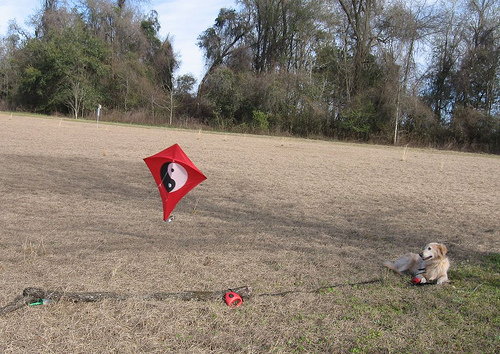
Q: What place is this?
A: It is a field.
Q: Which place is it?
A: It is a field.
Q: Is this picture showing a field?
A: Yes, it is showing a field.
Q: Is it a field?
A: Yes, it is a field.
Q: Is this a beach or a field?
A: It is a field.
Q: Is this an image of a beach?
A: No, the picture is showing a field.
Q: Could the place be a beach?
A: No, it is a field.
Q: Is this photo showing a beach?
A: No, the picture is showing a field.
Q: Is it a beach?
A: No, it is a field.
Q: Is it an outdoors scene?
A: Yes, it is outdoors.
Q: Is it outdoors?
A: Yes, it is outdoors.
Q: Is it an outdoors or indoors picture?
A: It is outdoors.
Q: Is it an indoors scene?
A: No, it is outdoors.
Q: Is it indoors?
A: No, it is outdoors.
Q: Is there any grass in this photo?
A: Yes, there is grass.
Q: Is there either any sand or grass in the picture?
A: Yes, there is grass.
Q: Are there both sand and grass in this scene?
A: No, there is grass but no sand.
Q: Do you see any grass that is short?
A: Yes, there is short grass.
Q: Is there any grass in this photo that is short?
A: Yes, there is grass that is short.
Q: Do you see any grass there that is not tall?
A: Yes, there is short grass.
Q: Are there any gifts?
A: No, there are no gifts.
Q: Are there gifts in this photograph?
A: No, there are no gifts.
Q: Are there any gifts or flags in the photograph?
A: No, there are no gifts or flags.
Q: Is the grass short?
A: Yes, the grass is short.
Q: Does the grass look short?
A: Yes, the grass is short.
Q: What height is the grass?
A: The grass is short.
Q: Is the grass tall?
A: No, the grass is short.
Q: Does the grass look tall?
A: No, the grass is short.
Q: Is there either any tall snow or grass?
A: No, there is grass but it is short.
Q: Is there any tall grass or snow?
A: No, there is grass but it is short.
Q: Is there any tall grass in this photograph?
A: No, there is grass but it is short.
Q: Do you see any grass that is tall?
A: No, there is grass but it is short.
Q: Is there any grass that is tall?
A: No, there is grass but it is short.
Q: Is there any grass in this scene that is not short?
A: No, there is grass but it is short.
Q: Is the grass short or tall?
A: The grass is short.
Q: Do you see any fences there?
A: No, there are no fences.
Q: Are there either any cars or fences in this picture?
A: No, there are no fences or cars.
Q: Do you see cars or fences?
A: No, there are no fences or cars.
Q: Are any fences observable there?
A: No, there are no fences.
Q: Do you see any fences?
A: No, there are no fences.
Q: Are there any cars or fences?
A: No, there are no fences or cars.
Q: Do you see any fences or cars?
A: No, there are no fences or cars.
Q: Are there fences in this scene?
A: No, there are no fences.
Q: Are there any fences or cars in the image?
A: No, there are no fences or cars.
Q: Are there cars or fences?
A: No, there are no fences or cars.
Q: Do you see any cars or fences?
A: No, there are no fences or cars.